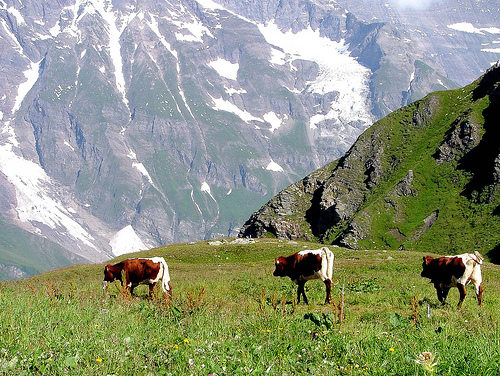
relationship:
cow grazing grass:
[94, 246, 200, 322] [156, 320, 336, 366]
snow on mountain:
[317, 76, 359, 105] [9, 1, 346, 167]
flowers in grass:
[307, 333, 439, 367] [38, 309, 191, 367]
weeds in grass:
[179, 338, 320, 365] [38, 309, 191, 367]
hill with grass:
[313, 121, 477, 231] [192, 305, 349, 360]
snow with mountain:
[269, 18, 337, 67] [3, 10, 376, 162]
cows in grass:
[97, 230, 498, 316] [58, 257, 413, 366]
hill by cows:
[238, 59, 498, 265] [78, 238, 477, 308]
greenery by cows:
[389, 137, 488, 237] [98, 248, 478, 313]